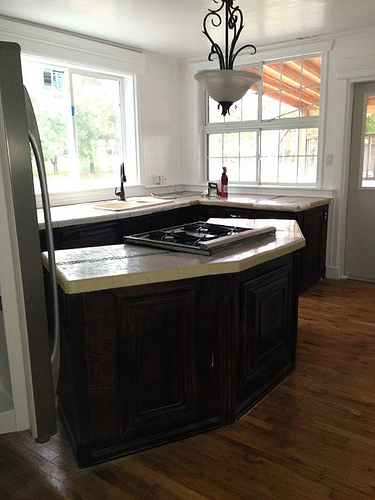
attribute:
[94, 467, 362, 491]
floor — hardwood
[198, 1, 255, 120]
fixture — drop light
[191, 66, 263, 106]
glass — school house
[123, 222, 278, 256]
stop top — four burner, gas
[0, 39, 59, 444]
refrigerator — brushed stainless steel, opened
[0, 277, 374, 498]
flooring — brown stained, wooden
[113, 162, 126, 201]
kitchen faucet — single handle, black, high access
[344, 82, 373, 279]
window door — grey painted, single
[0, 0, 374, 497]
kitchen — neat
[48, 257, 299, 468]
cabinets — wooden, dark brown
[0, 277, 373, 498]
floor — wooden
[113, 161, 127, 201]
faucet — black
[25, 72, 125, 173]
trees — green, leafy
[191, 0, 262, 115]
light fixture — drop, black metal, white glass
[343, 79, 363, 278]
door — cream colored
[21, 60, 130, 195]
window — paned, glass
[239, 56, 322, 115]
awning — red, yellow, orange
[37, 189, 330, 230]
countertop — cream colored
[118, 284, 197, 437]
cabinet door — dark, wooden, raised panel, false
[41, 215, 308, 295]
counter — tiled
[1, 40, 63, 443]
refrigerator door — silver, hanging around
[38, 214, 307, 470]
island — dark wooden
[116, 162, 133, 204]
faucet — black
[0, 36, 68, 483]
refrigerator door — open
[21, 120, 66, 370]
handle — gray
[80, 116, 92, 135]
leaves — green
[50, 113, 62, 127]
leaves — green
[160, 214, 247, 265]
burner — black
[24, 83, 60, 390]
handle — silver, fridge, refrigerator, door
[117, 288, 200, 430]
door — brown, cabinet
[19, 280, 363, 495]
floor — hard wood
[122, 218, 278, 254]
top — range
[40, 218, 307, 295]
counter top — island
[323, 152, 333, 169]
switch — light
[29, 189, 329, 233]
counter — kitchen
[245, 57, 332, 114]
beams — exposed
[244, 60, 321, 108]
roof — patio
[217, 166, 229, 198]
bottle — red, brown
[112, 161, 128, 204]
faucet — elegant, dark, metal, sink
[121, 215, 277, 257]
grill — four burner, gas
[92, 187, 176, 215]
sink — white, two compartment, kitchen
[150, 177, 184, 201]
cords — some, white, power